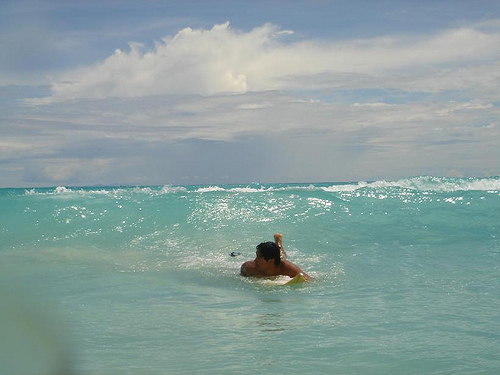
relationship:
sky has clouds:
[1, 3, 497, 186] [27, 19, 497, 187]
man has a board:
[239, 231, 310, 286] [270, 273, 306, 289]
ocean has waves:
[3, 177, 499, 374] [4, 175, 498, 268]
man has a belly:
[239, 231, 310, 286] [258, 274, 287, 278]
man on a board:
[239, 231, 310, 286] [254, 273, 290, 288]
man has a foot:
[239, 231, 310, 286] [274, 232, 280, 242]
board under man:
[254, 273, 290, 288] [239, 231, 310, 286]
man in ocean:
[239, 231, 310, 286] [3, 177, 499, 374]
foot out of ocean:
[274, 232, 280, 242] [0, 177, 499, 374]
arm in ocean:
[286, 277, 311, 292] [0, 177, 499, 374]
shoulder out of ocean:
[241, 260, 300, 275] [0, 177, 499, 374]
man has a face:
[239, 231, 310, 286] [255, 252, 268, 270]